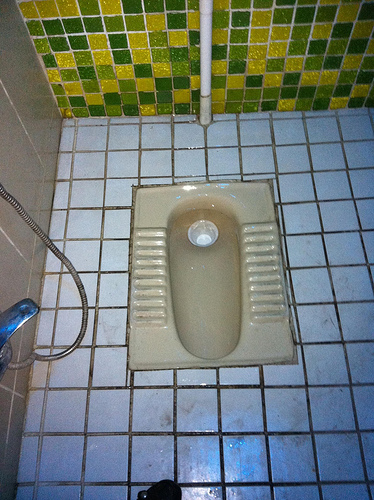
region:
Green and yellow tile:
[13, 0, 373, 129]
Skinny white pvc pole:
[198, 0, 221, 130]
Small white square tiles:
[11, 100, 373, 498]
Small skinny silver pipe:
[1, 175, 99, 379]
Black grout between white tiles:
[9, 106, 373, 498]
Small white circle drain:
[181, 213, 226, 252]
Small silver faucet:
[0, 277, 54, 372]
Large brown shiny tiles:
[0, 0, 67, 497]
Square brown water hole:
[121, 171, 305, 378]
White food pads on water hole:
[239, 210, 290, 336]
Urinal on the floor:
[103, 165, 309, 407]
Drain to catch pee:
[182, 214, 226, 251]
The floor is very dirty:
[149, 418, 261, 485]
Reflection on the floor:
[188, 421, 244, 491]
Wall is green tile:
[81, 10, 176, 99]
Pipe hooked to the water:
[13, 199, 132, 332]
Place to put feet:
[239, 214, 288, 328]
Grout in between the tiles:
[255, 406, 288, 468]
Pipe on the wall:
[187, 40, 228, 151]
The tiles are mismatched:
[70, 21, 207, 113]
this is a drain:
[112, 205, 313, 416]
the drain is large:
[166, 278, 299, 371]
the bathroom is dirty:
[46, 208, 318, 399]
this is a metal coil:
[32, 271, 138, 354]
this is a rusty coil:
[80, 288, 131, 406]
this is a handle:
[26, 305, 49, 357]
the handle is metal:
[1, 275, 84, 403]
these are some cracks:
[142, 418, 210, 455]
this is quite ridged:
[133, 272, 157, 337]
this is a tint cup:
[182, 214, 241, 244]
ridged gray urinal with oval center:
[123, 179, 295, 364]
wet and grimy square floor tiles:
[17, 110, 369, 490]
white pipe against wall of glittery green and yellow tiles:
[17, 0, 367, 110]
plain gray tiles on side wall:
[0, 7, 60, 491]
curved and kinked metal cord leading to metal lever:
[0, 184, 85, 365]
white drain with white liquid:
[187, 215, 215, 241]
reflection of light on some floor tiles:
[177, 441, 264, 493]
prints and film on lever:
[0, 295, 34, 337]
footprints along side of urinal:
[296, 228, 358, 471]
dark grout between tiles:
[67, 401, 333, 479]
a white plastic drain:
[187, 217, 219, 248]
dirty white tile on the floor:
[139, 390, 339, 455]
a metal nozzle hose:
[10, 198, 74, 271]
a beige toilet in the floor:
[120, 178, 314, 379]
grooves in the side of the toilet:
[247, 222, 283, 326]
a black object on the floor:
[128, 474, 190, 498]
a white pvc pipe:
[200, 21, 218, 134]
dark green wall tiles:
[45, 17, 80, 48]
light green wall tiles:
[150, 33, 169, 62]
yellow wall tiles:
[246, 27, 288, 58]